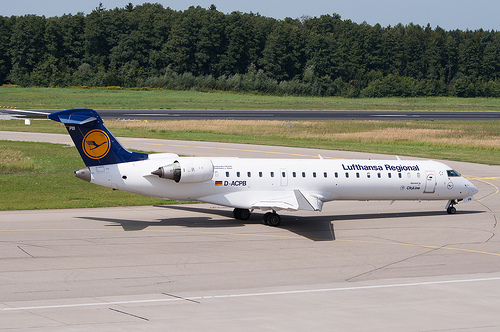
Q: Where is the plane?
A: Runway.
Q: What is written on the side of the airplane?
A: Lufthansa regional.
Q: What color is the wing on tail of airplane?
A: Blue with gold.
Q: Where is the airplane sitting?
A: On tarmac.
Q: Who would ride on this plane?
A: Travelers.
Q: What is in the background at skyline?
A: Trees.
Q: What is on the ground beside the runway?
A: Grass.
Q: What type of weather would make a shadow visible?
A: Sunny.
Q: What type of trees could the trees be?
A: Pine.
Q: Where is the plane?
A: On a runway.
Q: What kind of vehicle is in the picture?
A: Airplane.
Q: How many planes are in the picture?
A: 1.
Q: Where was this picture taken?
A: At the airport.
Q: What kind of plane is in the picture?
A: A jet.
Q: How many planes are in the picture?
A: One.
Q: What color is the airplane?
A: White.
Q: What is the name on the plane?
A: Lufthansa Regional.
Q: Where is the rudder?
A: On the top at the back.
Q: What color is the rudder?
A: Blue.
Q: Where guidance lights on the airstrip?
A: Behind the plane.